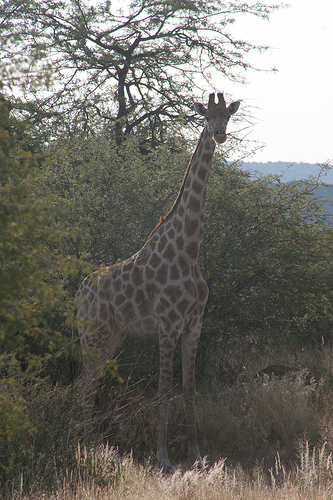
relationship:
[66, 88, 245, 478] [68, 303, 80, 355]
giraffe has a thin tail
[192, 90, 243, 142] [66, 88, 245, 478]
head on giraffe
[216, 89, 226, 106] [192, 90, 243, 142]
horn on head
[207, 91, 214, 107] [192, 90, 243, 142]
horn on head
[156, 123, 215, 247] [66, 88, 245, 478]
neck on giraffe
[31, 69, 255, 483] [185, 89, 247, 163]
giraffe has a head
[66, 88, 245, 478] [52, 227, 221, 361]
giraffe has a body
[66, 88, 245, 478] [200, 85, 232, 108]
giraffe has horns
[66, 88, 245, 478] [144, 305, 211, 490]
giraffe has legs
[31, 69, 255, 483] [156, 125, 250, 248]
giraffe has a neck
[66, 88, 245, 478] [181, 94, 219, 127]
giraffe has an ear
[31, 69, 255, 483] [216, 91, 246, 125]
giraffe has an ear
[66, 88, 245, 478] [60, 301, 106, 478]
giraffe has legs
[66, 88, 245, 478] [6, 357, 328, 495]
giraffe standing in yard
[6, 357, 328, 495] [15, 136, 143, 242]
yard with trees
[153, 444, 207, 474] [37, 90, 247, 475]
feet of giraffe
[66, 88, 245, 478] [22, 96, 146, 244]
giraffe standing in woods